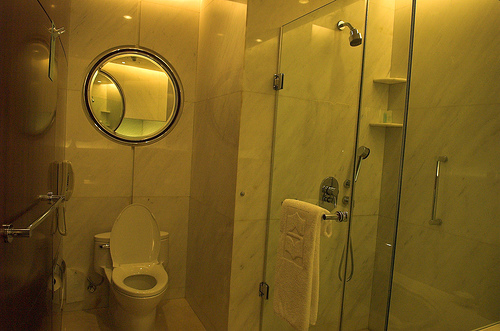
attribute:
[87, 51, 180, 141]
mirror — hanging, round, framed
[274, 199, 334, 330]
towel — hanging, white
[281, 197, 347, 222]
rack — silver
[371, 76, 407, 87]
shelf — hanging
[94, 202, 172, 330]
toilet — white, shiny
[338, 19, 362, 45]
shower head — hanging, silver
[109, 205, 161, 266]
lid — up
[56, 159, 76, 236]
telephone — white, hanging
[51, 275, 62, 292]
toilet paper — white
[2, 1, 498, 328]
bathroom — clean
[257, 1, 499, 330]
doors — glass